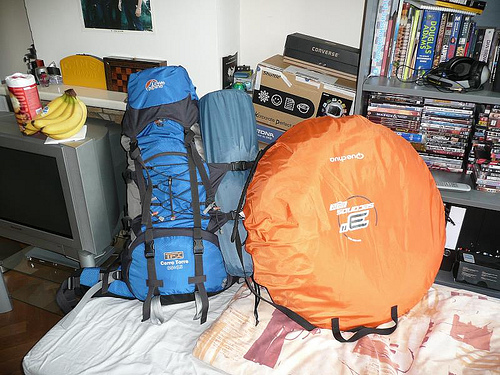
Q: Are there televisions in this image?
A: Yes, there is a television.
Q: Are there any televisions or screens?
A: Yes, there is a television.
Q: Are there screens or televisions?
A: Yes, there is a television.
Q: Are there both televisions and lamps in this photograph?
A: No, there is a television but no lamps.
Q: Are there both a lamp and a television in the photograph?
A: No, there is a television but no lamps.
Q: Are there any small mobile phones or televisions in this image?
A: Yes, there is a small television.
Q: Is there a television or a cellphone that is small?
A: Yes, the television is small.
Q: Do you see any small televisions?
A: Yes, there is a small television.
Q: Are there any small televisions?
A: Yes, there is a small television.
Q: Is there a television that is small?
A: Yes, there is a television that is small.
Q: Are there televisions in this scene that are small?
A: Yes, there is a television that is small.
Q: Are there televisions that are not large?
A: Yes, there is a small television.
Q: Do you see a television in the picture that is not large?
A: Yes, there is a small television.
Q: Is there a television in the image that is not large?
A: Yes, there is a small television.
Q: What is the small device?
A: The device is a television.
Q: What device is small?
A: The device is a television.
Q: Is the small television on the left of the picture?
A: Yes, the television is on the left of the image.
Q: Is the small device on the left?
A: Yes, the television is on the left of the image.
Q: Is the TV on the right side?
A: No, the TV is on the left of the image.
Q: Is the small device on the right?
A: No, the TV is on the left of the image.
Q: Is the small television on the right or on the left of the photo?
A: The television is on the left of the image.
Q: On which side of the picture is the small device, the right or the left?
A: The television is on the left of the image.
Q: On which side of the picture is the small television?
A: The TV is on the left of the image.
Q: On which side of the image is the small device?
A: The TV is on the left of the image.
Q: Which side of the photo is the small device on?
A: The TV is on the left of the image.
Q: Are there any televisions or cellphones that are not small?
A: No, there is a television but it is small.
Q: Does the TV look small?
A: Yes, the TV is small.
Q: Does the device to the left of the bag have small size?
A: Yes, the TV is small.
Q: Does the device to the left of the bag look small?
A: Yes, the TV is small.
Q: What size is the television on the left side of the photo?
A: The TV is small.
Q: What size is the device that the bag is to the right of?
A: The TV is small.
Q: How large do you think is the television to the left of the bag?
A: The television is small.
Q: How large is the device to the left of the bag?
A: The television is small.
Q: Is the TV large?
A: No, the TV is small.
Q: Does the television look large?
A: No, the television is small.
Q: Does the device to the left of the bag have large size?
A: No, the television is small.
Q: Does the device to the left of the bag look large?
A: No, the television is small.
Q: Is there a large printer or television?
A: No, there is a television but it is small.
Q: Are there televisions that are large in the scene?
A: No, there is a television but it is small.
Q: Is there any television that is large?
A: No, there is a television but it is small.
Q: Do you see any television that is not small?
A: No, there is a television but it is small.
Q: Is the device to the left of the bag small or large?
A: The television is small.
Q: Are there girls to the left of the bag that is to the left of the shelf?
A: No, there is a television to the left of the bag.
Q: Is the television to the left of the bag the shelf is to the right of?
A: Yes, the television is to the left of the bag.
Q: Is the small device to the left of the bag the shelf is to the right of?
A: Yes, the television is to the left of the bag.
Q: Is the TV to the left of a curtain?
A: No, the TV is to the left of the bag.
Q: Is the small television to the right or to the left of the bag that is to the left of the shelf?
A: The television is to the left of the bag.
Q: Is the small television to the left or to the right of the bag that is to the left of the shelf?
A: The television is to the left of the bag.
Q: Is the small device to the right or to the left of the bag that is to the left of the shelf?
A: The television is to the left of the bag.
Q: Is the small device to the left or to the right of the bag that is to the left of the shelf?
A: The television is to the left of the bag.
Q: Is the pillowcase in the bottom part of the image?
A: Yes, the pillowcase is in the bottom of the image.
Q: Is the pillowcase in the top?
A: No, the pillowcase is in the bottom of the image.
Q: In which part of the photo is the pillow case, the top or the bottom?
A: The pillow case is in the bottom of the image.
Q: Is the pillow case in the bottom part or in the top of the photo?
A: The pillow case is in the bottom of the image.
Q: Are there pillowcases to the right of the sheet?
A: Yes, there is a pillowcase to the right of the sheet.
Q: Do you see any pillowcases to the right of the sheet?
A: Yes, there is a pillowcase to the right of the sheet.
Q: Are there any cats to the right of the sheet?
A: No, there is a pillowcase to the right of the sheet.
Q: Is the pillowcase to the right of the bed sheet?
A: Yes, the pillowcase is to the right of the bed sheet.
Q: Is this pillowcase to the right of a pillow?
A: No, the pillowcase is to the right of the bed sheet.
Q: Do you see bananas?
A: Yes, there are bananas.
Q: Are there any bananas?
A: Yes, there are bananas.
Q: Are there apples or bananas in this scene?
A: Yes, there are bananas.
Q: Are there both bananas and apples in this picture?
A: No, there are bananas but no apples.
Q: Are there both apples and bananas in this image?
A: No, there are bananas but no apples.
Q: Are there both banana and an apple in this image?
A: No, there are bananas but no apples.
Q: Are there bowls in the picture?
A: No, there are no bowls.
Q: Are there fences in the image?
A: No, there are no fences.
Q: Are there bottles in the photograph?
A: No, there are no bottles.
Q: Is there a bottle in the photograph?
A: No, there are no bottles.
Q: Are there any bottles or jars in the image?
A: No, there are no bottles or jars.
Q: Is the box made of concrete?
A: No, the box is made of cardboard.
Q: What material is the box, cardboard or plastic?
A: The box is made of cardboard.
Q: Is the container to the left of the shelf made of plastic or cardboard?
A: The box is made of cardboard.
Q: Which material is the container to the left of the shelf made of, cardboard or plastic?
A: The box is made of cardboard.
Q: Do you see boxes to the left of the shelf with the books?
A: Yes, there is a box to the left of the shelf.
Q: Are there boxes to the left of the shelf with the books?
A: Yes, there is a box to the left of the shelf.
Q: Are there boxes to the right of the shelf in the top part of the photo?
A: No, the box is to the left of the shelf.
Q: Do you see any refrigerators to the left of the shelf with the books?
A: No, there is a box to the left of the shelf.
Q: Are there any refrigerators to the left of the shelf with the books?
A: No, there is a box to the left of the shelf.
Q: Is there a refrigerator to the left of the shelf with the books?
A: No, there is a box to the left of the shelf.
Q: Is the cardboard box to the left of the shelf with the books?
A: Yes, the box is to the left of the shelf.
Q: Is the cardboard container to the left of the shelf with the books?
A: Yes, the box is to the left of the shelf.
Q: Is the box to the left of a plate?
A: No, the box is to the left of the shelf.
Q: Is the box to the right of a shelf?
A: No, the box is to the left of a shelf.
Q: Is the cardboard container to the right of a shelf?
A: No, the box is to the left of a shelf.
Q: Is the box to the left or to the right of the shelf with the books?
A: The box is to the left of the shelf.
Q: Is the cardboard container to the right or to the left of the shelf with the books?
A: The box is to the left of the shelf.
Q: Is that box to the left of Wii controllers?
A: No, the box is to the left of the headphones.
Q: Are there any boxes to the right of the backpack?
A: Yes, there is a box to the right of the backpack.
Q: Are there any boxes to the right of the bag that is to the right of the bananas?
A: Yes, there is a box to the right of the backpack.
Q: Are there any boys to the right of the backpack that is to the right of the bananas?
A: No, there is a box to the right of the backpack.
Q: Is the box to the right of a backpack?
A: Yes, the box is to the right of a backpack.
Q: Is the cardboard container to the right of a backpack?
A: Yes, the box is to the right of a backpack.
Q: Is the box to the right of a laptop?
A: No, the box is to the right of a backpack.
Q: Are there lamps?
A: No, there are no lamps.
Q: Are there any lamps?
A: No, there are no lamps.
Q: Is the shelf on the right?
A: Yes, the shelf is on the right of the image.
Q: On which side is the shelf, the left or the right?
A: The shelf is on the right of the image.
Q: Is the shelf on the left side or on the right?
A: The shelf is on the right of the image.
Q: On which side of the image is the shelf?
A: The shelf is on the right of the image.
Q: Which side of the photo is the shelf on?
A: The shelf is on the right of the image.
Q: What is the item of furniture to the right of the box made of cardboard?
A: The piece of furniture is a shelf.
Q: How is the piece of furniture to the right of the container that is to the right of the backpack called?
A: The piece of furniture is a shelf.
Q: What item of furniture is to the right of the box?
A: The piece of furniture is a shelf.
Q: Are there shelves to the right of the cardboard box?
A: Yes, there is a shelf to the right of the box.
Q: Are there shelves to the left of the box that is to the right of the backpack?
A: No, the shelf is to the right of the box.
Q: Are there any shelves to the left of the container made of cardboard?
A: No, the shelf is to the right of the box.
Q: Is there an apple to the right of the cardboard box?
A: No, there is a shelf to the right of the box.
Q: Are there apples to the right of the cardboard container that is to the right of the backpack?
A: No, there is a shelf to the right of the box.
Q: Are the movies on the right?
A: Yes, the movies are on the right of the image.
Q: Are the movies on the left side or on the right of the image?
A: The movies are on the right of the image.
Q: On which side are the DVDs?
A: The DVDs are on the right of the image.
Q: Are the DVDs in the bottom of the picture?
A: No, the DVDs are in the top of the image.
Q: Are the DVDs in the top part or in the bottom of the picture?
A: The DVDs are in the top of the image.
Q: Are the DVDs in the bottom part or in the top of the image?
A: The DVDs are in the top of the image.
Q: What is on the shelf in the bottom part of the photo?
A: The DVDs are on the shelf.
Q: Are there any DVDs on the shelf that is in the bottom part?
A: Yes, there are DVDs on the shelf.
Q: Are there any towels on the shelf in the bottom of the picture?
A: No, there are DVDs on the shelf.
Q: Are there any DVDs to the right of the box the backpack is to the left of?
A: Yes, there are DVDs to the right of the box.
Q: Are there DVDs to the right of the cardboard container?
A: Yes, there are DVDs to the right of the box.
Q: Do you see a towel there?
A: No, there are no towels.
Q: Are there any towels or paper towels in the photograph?
A: No, there are no towels or paper towels.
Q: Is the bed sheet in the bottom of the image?
A: Yes, the bed sheet is in the bottom of the image.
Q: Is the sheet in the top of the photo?
A: No, the sheet is in the bottom of the image.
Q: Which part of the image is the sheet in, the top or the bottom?
A: The sheet is in the bottom of the image.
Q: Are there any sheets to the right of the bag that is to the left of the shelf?
A: No, the sheet is to the left of the bag.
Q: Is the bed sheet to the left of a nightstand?
A: No, the bed sheet is to the left of the bag.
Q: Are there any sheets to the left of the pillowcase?
A: Yes, there is a sheet to the left of the pillowcase.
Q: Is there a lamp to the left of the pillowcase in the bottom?
A: No, there is a sheet to the left of the pillow case.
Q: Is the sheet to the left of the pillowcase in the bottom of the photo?
A: Yes, the sheet is to the left of the pillowcase.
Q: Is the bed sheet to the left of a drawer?
A: No, the bed sheet is to the left of the pillowcase.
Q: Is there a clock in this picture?
A: No, there are no clocks.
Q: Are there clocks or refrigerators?
A: No, there are no clocks or refrigerators.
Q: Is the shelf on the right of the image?
A: Yes, the shelf is on the right of the image.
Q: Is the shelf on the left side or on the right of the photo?
A: The shelf is on the right of the image.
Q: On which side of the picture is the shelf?
A: The shelf is on the right of the image.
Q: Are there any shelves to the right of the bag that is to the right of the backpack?
A: Yes, there is a shelf to the right of the bag.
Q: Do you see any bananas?
A: Yes, there are bananas.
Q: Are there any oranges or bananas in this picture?
A: Yes, there are bananas.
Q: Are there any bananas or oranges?
A: Yes, there are bananas.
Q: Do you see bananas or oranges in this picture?
A: Yes, there are bananas.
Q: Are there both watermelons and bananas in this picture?
A: No, there are bananas but no watermelons.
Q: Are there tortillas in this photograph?
A: No, there are no tortillas.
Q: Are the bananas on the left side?
A: Yes, the bananas are on the left of the image.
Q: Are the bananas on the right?
A: No, the bananas are on the left of the image.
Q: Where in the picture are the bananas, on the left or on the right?
A: The bananas are on the left of the image.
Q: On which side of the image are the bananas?
A: The bananas are on the left of the image.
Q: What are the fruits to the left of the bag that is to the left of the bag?
A: The fruits are bananas.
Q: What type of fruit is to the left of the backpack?
A: The fruits are bananas.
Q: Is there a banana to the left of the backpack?
A: Yes, there are bananas to the left of the backpack.